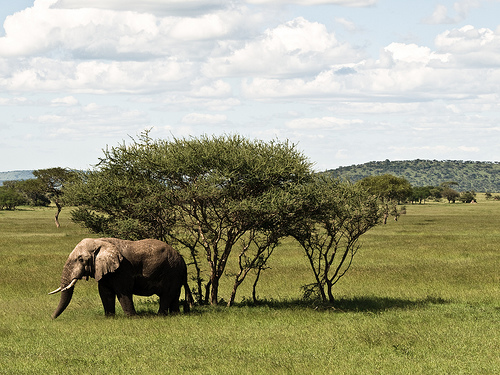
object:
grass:
[219, 310, 280, 330]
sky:
[0, 0, 500, 175]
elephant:
[47, 238, 198, 319]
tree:
[58, 125, 306, 308]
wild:
[0, 192, 498, 375]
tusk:
[60, 277, 78, 293]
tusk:
[46, 284, 63, 296]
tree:
[373, 175, 388, 206]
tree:
[358, 171, 413, 203]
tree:
[31, 167, 88, 228]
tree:
[0, 183, 32, 216]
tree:
[388, 196, 401, 223]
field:
[0, 192, 499, 375]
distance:
[0, 153, 499, 208]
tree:
[416, 186, 431, 204]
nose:
[50, 265, 77, 320]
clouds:
[342, 17, 496, 86]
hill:
[306, 157, 499, 192]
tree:
[481, 187, 492, 203]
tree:
[444, 188, 458, 204]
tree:
[282, 175, 393, 314]